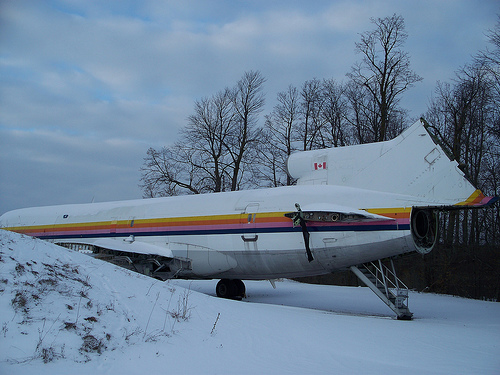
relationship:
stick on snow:
[205, 308, 222, 342] [0, 229, 496, 374]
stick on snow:
[183, 291, 190, 319] [0, 229, 496, 374]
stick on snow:
[180, 287, 184, 317] [0, 229, 496, 374]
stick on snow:
[175, 296, 180, 320] [0, 229, 496, 374]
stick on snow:
[147, 288, 162, 323] [0, 229, 496, 374]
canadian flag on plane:
[310, 156, 336, 176] [21, 117, 491, 322]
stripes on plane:
[1, 205, 411, 239] [21, 117, 491, 322]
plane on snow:
[21, 117, 491, 322] [2, 274, 497, 374]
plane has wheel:
[0, 117, 493, 322] [206, 270, 252, 300]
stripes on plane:
[18, 203, 407, 243] [21, 117, 491, 322]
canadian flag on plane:
[310, 161, 327, 171] [1, 102, 471, 288]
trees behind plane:
[137, 13, 497, 245] [21, 117, 491, 322]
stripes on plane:
[3, 189, 496, 241] [21, 117, 491, 322]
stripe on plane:
[233, 217, 273, 236] [90, 157, 452, 313]